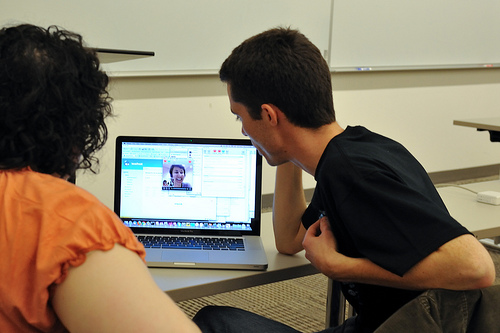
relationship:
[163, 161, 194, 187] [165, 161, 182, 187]
face of a boy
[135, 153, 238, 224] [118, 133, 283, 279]
picture in a computer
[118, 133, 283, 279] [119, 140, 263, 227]
cool computer screen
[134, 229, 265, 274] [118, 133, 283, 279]
keyboard connected to computer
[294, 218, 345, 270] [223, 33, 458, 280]
hand of a person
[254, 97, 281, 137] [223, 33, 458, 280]
ear of a person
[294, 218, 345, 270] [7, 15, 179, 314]
hand of a girl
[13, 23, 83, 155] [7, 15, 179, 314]
hair of a girl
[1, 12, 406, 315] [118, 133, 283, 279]
two people watching computer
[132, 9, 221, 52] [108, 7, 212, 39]
part of a white dry erase board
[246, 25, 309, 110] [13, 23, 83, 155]
man's short cut hair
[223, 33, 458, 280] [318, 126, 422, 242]
par of a man's black shirt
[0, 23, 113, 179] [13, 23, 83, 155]
hair curly hair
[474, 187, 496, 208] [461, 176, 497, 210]
white computer mouse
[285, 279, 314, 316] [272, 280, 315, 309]
portion of carpet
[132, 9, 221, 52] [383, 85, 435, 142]
part of a white painted wall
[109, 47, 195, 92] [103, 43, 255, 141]
blue and white marker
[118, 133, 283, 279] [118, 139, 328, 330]
small laptop computer on deck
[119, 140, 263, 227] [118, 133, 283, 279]
screen of laptop computer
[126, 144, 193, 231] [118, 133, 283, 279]
skype on computer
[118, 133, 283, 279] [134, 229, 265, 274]
black computer keyboard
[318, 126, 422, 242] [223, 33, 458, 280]
black shirt on man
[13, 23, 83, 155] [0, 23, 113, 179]
curly black hair on hair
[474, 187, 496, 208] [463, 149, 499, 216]
white power supply on table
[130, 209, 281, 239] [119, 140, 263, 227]
tabs open at bottom of screen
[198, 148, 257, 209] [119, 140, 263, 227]
text box open on screen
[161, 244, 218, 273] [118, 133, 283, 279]
silver track pad on computer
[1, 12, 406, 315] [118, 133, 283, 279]
man and woman looking at computer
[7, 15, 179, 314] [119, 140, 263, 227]
woman on computer screen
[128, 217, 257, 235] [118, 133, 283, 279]
multiple icons at bottom of computer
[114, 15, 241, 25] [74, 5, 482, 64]
dry erase board in background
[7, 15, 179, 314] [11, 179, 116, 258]
woman wearing orange shirt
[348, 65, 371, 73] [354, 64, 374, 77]
blue dry erase market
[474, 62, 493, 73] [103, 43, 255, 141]
orange dry erase marker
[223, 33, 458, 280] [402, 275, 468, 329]
guy has jacket draped on bac of chair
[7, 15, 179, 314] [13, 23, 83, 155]
woman has curly hair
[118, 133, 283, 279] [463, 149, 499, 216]
laptop sitting on table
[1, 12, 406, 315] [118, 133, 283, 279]
people in front of a laptop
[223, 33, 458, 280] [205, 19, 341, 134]
man has black hair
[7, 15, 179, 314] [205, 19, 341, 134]
woman has black hair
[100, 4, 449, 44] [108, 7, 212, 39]
large white board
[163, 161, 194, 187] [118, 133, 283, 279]
woman in a screen of laptop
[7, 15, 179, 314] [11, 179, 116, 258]
woman wears an orange blouse